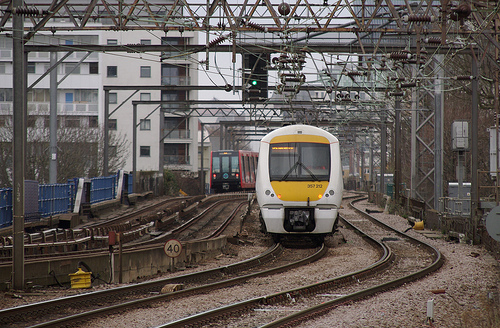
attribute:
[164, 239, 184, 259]
sign — round, round shaped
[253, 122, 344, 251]
train — yellow, white, pictured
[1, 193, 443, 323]
railroad track — pictured, curved, pictured here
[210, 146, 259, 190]
train — red, shown here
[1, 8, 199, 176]
building — tall, in the background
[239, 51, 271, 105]
train signal — electronic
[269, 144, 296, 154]
sign — pictured here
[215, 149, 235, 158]
sign — pictured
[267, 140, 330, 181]
windshield — made of glass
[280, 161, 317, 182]
windshield wipers — pictured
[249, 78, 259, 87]
traffic light — green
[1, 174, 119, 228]
fence — blue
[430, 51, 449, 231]
steel beam — pictured